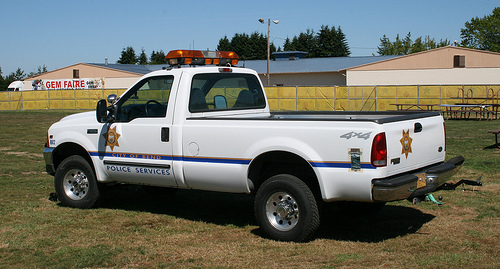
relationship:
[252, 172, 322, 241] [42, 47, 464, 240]
wheel of pick up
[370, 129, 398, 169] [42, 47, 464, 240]
light on pick up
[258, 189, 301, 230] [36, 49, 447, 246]
rim on truck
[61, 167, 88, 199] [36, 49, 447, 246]
rim on truck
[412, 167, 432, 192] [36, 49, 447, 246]
license plate on truck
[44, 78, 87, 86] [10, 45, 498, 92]
banner on building